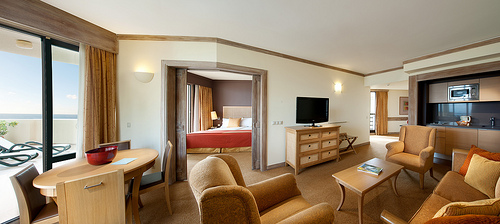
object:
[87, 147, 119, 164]
bowl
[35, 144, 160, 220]
table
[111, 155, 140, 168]
paper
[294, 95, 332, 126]
t.v.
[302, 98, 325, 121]
screen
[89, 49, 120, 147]
curtain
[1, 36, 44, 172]
window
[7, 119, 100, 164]
deck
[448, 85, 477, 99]
microwave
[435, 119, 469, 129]
sink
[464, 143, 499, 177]
pillow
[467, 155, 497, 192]
pillow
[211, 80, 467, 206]
livingroom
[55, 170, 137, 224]
chair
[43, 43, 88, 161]
door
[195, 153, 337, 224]
chair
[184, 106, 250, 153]
bed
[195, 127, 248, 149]
cover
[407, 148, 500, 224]
couch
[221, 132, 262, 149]
sheets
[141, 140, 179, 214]
chair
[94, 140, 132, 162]
chair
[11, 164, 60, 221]
chair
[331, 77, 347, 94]
light-fixture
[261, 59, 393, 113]
wall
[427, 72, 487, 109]
wall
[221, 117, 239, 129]
pillow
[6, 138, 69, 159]
chair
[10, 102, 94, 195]
patio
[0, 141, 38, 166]
chair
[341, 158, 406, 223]
coffee-table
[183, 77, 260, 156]
bedroom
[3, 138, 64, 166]
chaise-lounge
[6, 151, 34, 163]
chaise-lounge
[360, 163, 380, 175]
book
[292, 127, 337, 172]
chest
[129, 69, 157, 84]
light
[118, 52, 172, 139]
wall